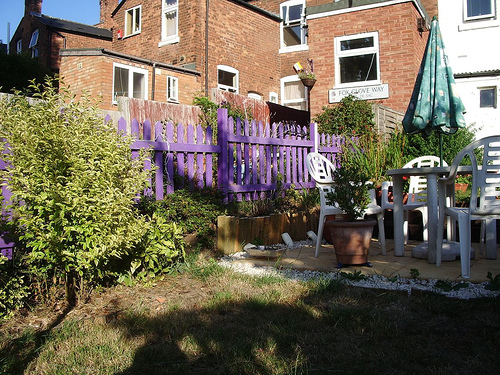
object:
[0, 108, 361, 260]
picket fence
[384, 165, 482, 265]
table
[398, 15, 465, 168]
umbrella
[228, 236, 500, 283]
slab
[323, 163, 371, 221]
plant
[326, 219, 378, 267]
pot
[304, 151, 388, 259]
chair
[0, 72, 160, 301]
bush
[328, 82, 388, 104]
sign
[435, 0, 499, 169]
building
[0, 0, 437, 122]
red bricks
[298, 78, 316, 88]
basket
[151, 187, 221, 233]
shrubs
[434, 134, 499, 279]
furniture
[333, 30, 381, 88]
window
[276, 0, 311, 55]
white frame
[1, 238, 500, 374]
shadows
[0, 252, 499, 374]
ground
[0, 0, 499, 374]
back yard